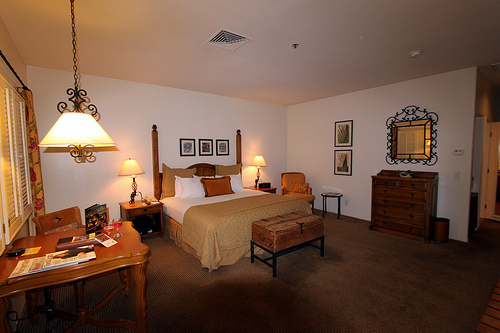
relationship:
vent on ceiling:
[212, 32, 242, 50] [183, 2, 283, 80]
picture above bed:
[218, 138, 231, 157] [147, 130, 297, 232]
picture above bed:
[199, 139, 212, 158] [147, 130, 297, 232]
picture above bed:
[178, 135, 195, 157] [147, 130, 297, 232]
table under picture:
[321, 191, 344, 217] [334, 151, 354, 176]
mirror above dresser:
[380, 117, 440, 164] [367, 178, 432, 238]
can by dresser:
[431, 214, 448, 246] [367, 178, 432, 238]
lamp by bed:
[254, 156, 264, 185] [147, 130, 297, 232]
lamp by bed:
[122, 164, 142, 200] [147, 130, 297, 232]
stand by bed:
[123, 202, 162, 226] [147, 130, 297, 232]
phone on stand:
[145, 193, 156, 205] [123, 202, 162, 226]